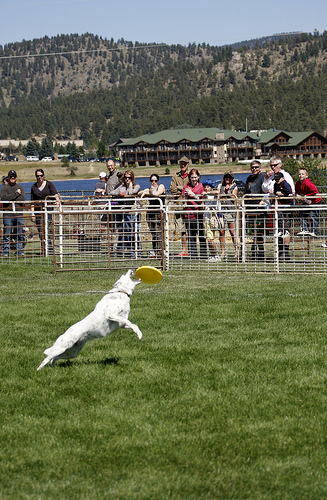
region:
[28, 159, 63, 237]
person standing at gate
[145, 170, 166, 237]
person standing at gate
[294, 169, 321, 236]
person standing at gate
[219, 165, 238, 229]
person standing at gate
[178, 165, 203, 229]
person standing at gate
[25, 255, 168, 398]
white dog catching frisbee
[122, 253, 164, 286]
yellow frisbee in mouth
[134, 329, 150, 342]
paw of white dog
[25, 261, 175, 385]
A dog running and about to catch a frisbee.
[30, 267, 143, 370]
A white dog in midair.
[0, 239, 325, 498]
The plush grass.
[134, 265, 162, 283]
A yellow frisbee.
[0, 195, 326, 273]
A metal fence.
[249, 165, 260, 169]
A pair of dark colored sunglasses.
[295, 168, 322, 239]
A young boy in a red top and blue bottoms hanging over the fence.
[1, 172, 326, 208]
A dark body of water.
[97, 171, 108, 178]
The back of a white ball cap.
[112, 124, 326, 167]
A large brown and beige building.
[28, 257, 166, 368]
white dog catching yellow frisbee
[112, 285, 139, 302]
collar of white dog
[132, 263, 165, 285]
yellow frisbee being chased by dog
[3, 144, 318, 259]
crowd watching the dog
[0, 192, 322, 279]
white fence behind dog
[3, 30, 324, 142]
mountains covered in trees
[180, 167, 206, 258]
lady wearing pink shirt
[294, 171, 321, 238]
child wearing red shirt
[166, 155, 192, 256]
man wearing beige pullover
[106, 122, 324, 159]
green roofed building in background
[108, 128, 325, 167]
A large building with green roof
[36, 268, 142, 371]
A white dog catching a frisbee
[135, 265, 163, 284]
A yellow frisbee in the air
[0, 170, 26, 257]
A man with a black ball cap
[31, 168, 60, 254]
A woman wearing sunglasses and black shirt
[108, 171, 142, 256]
A woman leaning on the fence with a gray shirt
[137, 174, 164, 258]
A dark haired woman with sunglasses leaning on the fence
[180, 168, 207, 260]
A red haired woman wearing a red shirt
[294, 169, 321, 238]
A young boy standing on the fence with a red shirt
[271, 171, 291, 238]
A young boy standing on the fence with a black ballcap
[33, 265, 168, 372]
Dog catching frisbee.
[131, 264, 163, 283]
Yellow frisbee in the air.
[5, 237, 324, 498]
Grassy area with dog.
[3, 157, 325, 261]
Spectators watching dog.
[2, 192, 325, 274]
White fence separating dog and people.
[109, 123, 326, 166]
Hotel in the background.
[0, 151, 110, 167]
Parking lot in the background.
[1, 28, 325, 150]
Mountains in the background.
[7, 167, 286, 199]
Lake behind the spectators.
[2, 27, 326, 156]
Trees on the mountains.